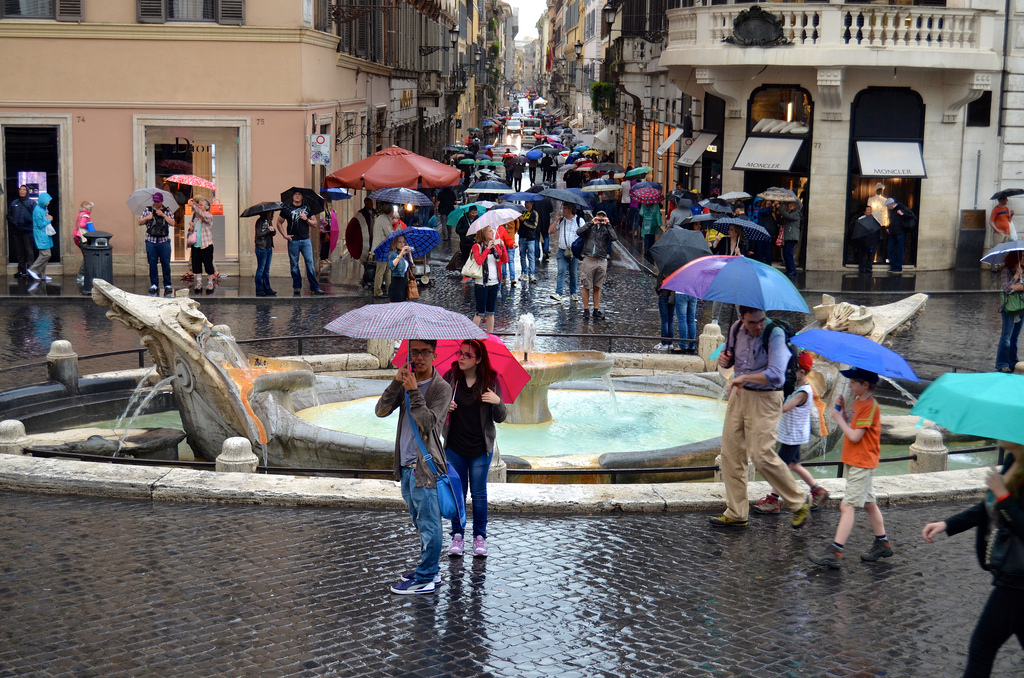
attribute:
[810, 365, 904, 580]
boy — young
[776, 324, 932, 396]
umbrella — blue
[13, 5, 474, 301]
building — peach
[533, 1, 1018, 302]
building — white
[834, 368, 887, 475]
shirt — orange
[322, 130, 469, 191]
umbrella — large, red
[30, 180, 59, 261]
jacket — blue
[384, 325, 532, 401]
umbrella — red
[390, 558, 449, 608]
shoe — grey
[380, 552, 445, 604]
shoe — grey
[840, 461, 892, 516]
shorts — tan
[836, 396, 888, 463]
shirt — orange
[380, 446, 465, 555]
jeans — blue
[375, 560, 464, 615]
shoe — grey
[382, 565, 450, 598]
shoe — grey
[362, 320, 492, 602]
man — blue